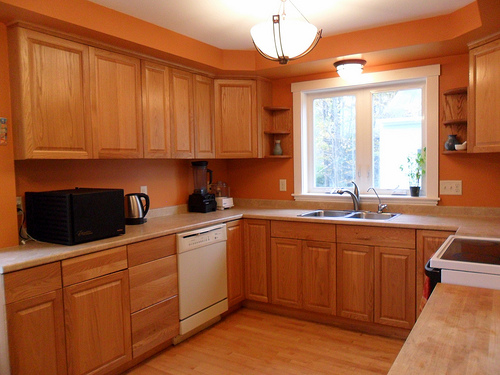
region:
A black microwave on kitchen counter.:
[20, 181, 125, 246]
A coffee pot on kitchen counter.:
[125, 187, 155, 222]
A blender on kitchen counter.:
[185, 160, 216, 210]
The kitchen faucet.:
[336, 180, 391, 215]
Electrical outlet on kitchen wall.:
[438, 176, 465, 197]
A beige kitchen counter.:
[380, 280, 496, 371]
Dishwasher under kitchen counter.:
[171, 216, 228, 336]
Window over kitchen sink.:
[290, 65, 436, 200]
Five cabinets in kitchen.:
[13, 21, 215, 163]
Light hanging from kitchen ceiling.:
[243, 6, 328, 65]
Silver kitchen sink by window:
[293, 180, 403, 230]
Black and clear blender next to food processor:
[185, 156, 215, 211]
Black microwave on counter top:
[20, 186, 130, 241]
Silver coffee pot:
[121, 187, 152, 227]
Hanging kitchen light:
[241, 7, 322, 64]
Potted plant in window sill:
[392, 145, 435, 198]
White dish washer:
[166, 220, 229, 345]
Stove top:
[420, 227, 496, 292]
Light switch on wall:
[435, 176, 463, 197]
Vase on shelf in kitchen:
[271, 135, 286, 158]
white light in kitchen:
[243, 16, 330, 85]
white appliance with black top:
[423, 226, 498, 281]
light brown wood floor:
[226, 319, 375, 367]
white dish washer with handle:
[176, 227, 243, 342]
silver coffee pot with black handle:
[121, 187, 158, 233]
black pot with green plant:
[402, 147, 437, 206]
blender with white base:
[213, 169, 250, 219]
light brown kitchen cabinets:
[3, 3, 273, 165]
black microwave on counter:
[26, 185, 136, 247]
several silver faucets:
[328, 177, 405, 217]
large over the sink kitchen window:
[284, 68, 455, 219]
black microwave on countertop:
[11, 161, 138, 256]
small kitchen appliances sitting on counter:
[180, 151, 244, 226]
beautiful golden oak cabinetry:
[71, 43, 291, 356]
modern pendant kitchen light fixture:
[246, 5, 331, 77]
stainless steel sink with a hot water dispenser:
[294, 175, 402, 242]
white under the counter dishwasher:
[168, 215, 252, 350]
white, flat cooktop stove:
[414, 226, 498, 304]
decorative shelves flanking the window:
[264, 80, 471, 177]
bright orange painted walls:
[223, 153, 300, 210]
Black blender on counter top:
[185, 155, 215, 206]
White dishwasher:
[175, 221, 225, 333]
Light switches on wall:
[436, 177, 456, 192]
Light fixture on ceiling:
[247, 0, 318, 61]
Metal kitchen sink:
[295, 180, 391, 216]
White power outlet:
[277, 176, 282, 186]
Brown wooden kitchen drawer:
[126, 249, 179, 310]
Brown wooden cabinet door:
[300, 240, 335, 305]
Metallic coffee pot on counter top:
[121, 190, 146, 220]